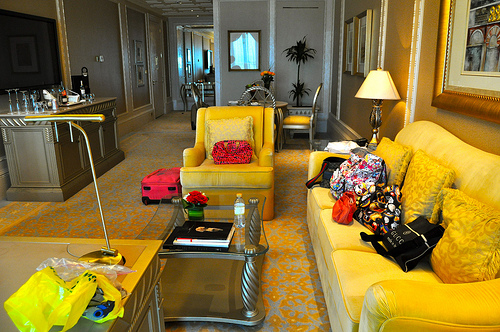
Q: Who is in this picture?
A: No one.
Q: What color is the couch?
A: Yellow.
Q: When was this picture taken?
A: Daytime.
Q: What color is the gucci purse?
A: Black.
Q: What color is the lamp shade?
A: White.